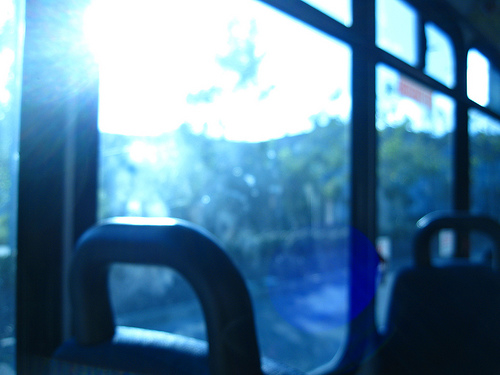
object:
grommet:
[330, 348, 353, 369]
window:
[467, 47, 490, 108]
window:
[424, 21, 455, 91]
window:
[373, 0, 418, 70]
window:
[300, 0, 354, 28]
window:
[373, 59, 455, 335]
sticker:
[399, 74, 433, 110]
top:
[85, 216, 186, 243]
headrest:
[68, 216, 261, 374]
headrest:
[413, 209, 499, 269]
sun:
[81, 0, 249, 119]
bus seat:
[381, 209, 499, 373]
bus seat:
[48, 216, 310, 374]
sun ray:
[34, 0, 226, 136]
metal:
[352, 0, 376, 360]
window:
[98, 0, 350, 374]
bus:
[0, 0, 499, 374]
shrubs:
[99, 115, 499, 312]